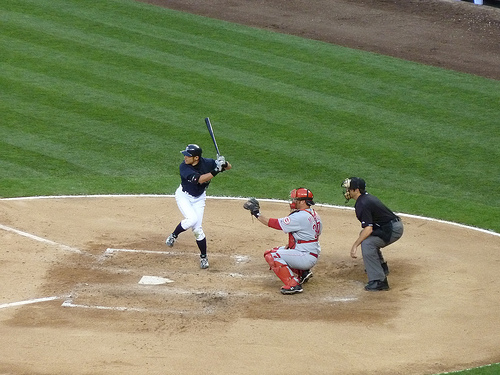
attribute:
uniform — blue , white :
[171, 156, 230, 258]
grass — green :
[14, 4, 496, 227]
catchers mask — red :
[262, 172, 329, 316]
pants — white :
[173, 184, 206, 242]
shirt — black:
[164, 160, 236, 200]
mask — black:
[338, 178, 350, 202]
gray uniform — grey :
[277, 207, 322, 267]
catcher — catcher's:
[245, 187, 322, 292]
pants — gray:
[359, 217, 405, 284]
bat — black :
[198, 102, 228, 169]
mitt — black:
[244, 197, 260, 215]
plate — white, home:
[136, 271, 173, 284]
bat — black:
[202, 115, 222, 156]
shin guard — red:
[262, 249, 295, 290]